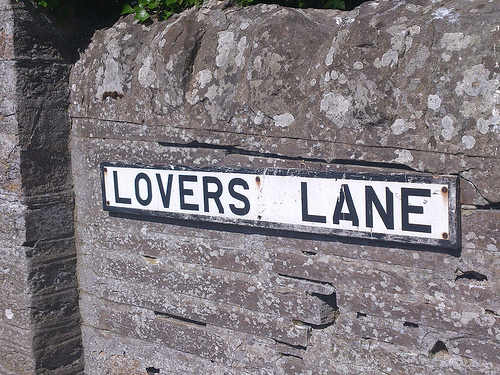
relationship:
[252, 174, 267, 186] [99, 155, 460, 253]
bolts hold sign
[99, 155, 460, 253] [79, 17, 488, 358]
sign attaches to wall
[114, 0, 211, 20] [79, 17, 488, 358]
trees behind wall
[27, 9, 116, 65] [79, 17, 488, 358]
shadow on wall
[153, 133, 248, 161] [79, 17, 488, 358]
crack in wall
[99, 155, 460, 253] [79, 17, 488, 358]
sign on wall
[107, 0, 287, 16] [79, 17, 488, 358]
leaves are behind wall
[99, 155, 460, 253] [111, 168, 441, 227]
sign says lovers lane